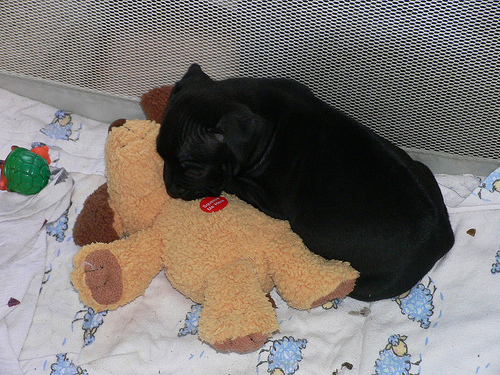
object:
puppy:
[157, 64, 454, 300]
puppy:
[72, 85, 360, 353]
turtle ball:
[0, 145, 50, 194]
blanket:
[1, 87, 499, 373]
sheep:
[375, 334, 420, 374]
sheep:
[40, 110, 82, 140]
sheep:
[71, 309, 106, 345]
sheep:
[392, 276, 439, 328]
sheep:
[50, 352, 84, 374]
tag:
[199, 196, 228, 211]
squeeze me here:
[203, 198, 224, 211]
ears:
[76, 183, 119, 243]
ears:
[141, 84, 169, 123]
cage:
[1, 0, 499, 179]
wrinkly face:
[159, 115, 219, 197]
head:
[106, 119, 165, 233]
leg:
[196, 276, 277, 342]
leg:
[278, 252, 360, 309]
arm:
[110, 229, 160, 306]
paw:
[85, 250, 124, 305]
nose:
[109, 119, 124, 130]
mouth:
[115, 127, 157, 149]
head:
[156, 79, 236, 201]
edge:
[1, 72, 499, 177]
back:
[238, 87, 436, 242]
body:
[233, 78, 455, 300]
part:
[445, 310, 498, 374]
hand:
[71, 243, 139, 310]